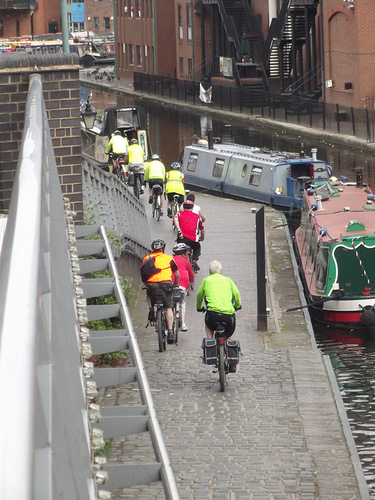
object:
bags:
[139, 255, 161, 282]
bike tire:
[218, 342, 225, 392]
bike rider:
[197, 258, 241, 373]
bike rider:
[141, 238, 180, 345]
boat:
[294, 178, 374, 323]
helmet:
[170, 242, 187, 255]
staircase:
[216, 1, 272, 106]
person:
[164, 161, 186, 219]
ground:
[295, 145, 306, 161]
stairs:
[282, 65, 321, 114]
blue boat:
[179, 139, 348, 217]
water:
[315, 334, 374, 499]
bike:
[196, 301, 242, 392]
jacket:
[196, 272, 241, 316]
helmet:
[150, 238, 166, 250]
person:
[171, 242, 195, 331]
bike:
[170, 289, 182, 343]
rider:
[179, 192, 206, 234]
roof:
[305, 180, 374, 245]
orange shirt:
[140, 252, 178, 283]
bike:
[142, 282, 180, 351]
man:
[172, 197, 205, 271]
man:
[141, 154, 166, 216]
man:
[123, 143, 147, 195]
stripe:
[315, 310, 363, 321]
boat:
[80, 104, 153, 169]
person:
[106, 130, 130, 175]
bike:
[104, 152, 128, 186]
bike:
[125, 161, 144, 200]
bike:
[143, 177, 164, 223]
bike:
[163, 191, 181, 231]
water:
[115, 98, 191, 151]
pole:
[60, 0, 70, 54]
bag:
[202, 336, 218, 364]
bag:
[225, 338, 239, 366]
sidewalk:
[95, 172, 370, 498]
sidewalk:
[75, 63, 374, 148]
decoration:
[351, 235, 371, 286]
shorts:
[204, 309, 236, 338]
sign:
[69, 3, 84, 24]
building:
[113, 0, 374, 127]